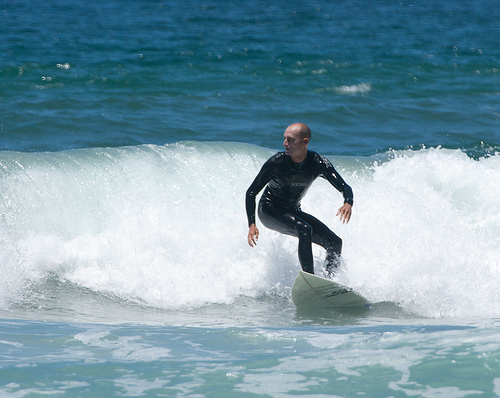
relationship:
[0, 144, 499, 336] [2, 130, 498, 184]
wave has top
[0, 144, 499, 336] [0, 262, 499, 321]
wave has bottom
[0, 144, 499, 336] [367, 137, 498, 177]
wave has part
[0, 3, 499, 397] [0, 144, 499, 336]
ocean has wave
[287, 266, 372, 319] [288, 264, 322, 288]
board has tip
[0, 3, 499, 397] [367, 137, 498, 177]
ocean has part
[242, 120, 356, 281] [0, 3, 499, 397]
man surfing in ocean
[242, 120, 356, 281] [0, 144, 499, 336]
man surfing on wave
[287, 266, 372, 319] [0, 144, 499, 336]
board floating on wave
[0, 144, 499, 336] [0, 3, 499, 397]
wave breaking in ocean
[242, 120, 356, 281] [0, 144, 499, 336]
man waiting for wave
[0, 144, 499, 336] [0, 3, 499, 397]
wave forming in ocean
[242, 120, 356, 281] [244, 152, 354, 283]
man wearing suit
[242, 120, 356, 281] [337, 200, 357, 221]
man has hand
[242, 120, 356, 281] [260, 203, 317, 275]
man has leg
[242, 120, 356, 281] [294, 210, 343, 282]
man has leg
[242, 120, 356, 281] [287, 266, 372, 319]
man on top of board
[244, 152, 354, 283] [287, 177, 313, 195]
suit says xcel